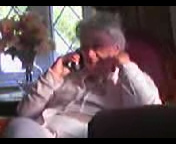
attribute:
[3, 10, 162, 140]
woman — sitting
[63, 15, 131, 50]
hair — gray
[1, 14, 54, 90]
flowers — pink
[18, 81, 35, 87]
rocks — white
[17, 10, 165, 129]
scene — blurry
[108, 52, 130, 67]
hand — curled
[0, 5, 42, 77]
window — glass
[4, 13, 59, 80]
flowers — pink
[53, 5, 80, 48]
pattern — diamond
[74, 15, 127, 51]
hair — white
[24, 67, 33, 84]
stems — narrow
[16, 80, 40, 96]
vase — glass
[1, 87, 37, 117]
table — dark